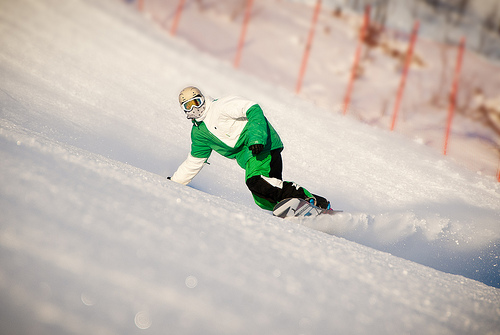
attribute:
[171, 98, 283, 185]
jacket — green, white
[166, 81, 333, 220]
man — green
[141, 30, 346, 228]
man — snowboarding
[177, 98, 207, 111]
goggles — white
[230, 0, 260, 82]
pole — orange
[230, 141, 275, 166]
glove — black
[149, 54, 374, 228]
man — black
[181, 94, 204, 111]
goggles — white, yellow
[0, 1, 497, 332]
snow — blowing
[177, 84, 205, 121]
helmet — white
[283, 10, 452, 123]
netting — orange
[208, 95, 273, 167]
jacket — green, white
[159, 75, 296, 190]
jacket — white, green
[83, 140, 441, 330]
snow — white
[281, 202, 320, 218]
writing — white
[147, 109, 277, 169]
jacket — white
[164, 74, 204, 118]
face gear — white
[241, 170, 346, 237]
pants — white